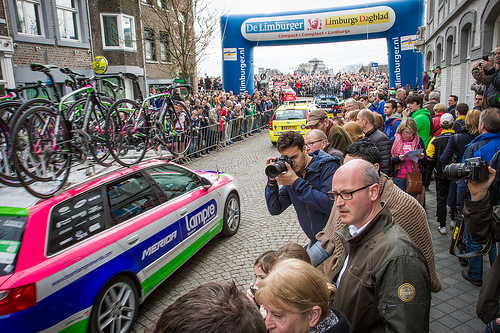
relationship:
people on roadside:
[149, 66, 496, 331] [272, 87, 498, 332]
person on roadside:
[252, 257, 337, 332] [272, 87, 498, 332]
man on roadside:
[329, 159, 431, 333] [272, 87, 498, 332]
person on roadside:
[267, 132, 341, 242] [272, 87, 498, 332]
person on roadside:
[460, 108, 497, 228] [272, 87, 498, 332]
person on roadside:
[426, 110, 456, 233] [272, 87, 498, 332]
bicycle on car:
[0, 63, 195, 200] [10, 160, 244, 322]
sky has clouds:
[190, 0, 422, 78] [277, 46, 286, 57]